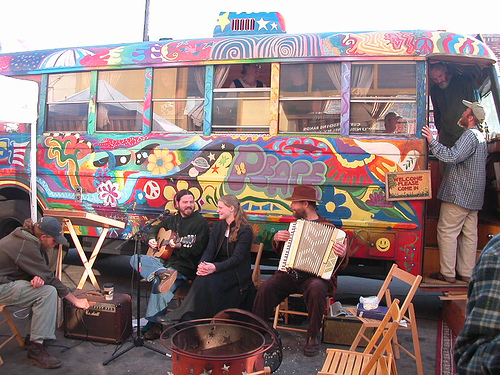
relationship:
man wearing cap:
[0, 215, 90, 368] [33, 211, 71, 251]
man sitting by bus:
[129, 189, 210, 340] [1, 6, 496, 252]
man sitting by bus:
[0, 215, 90, 368] [1, 6, 496, 252]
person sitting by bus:
[156, 193, 256, 330] [1, 6, 496, 252]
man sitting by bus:
[248, 184, 348, 357] [1, 6, 496, 252]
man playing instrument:
[248, 184, 348, 357] [277, 219, 345, 279]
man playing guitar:
[129, 189, 210, 340] [145, 225, 197, 257]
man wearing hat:
[425, 95, 488, 281] [456, 93, 493, 122]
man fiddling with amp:
[2, 216, 98, 350] [63, 288, 133, 343]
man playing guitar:
[129, 189, 210, 340] [138, 221, 201, 261]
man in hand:
[269, 188, 339, 334] [168, 239, 177, 249]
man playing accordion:
[269, 188, 339, 334] [261, 216, 374, 285]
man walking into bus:
[420, 100, 487, 284] [1, 6, 496, 252]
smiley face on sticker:
[376, 229, 388, 257] [375, 235, 391, 253]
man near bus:
[0, 215, 90, 368] [0, 7, 498, 279]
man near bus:
[129, 189, 210, 340] [0, 7, 498, 279]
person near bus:
[156, 193, 256, 330] [0, 7, 498, 279]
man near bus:
[248, 184, 348, 357] [0, 7, 498, 279]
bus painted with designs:
[0, 7, 498, 279] [66, 132, 183, 175]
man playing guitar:
[132, 186, 194, 342] [134, 218, 220, 258]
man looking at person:
[129, 189, 210, 340] [144, 194, 255, 330]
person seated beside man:
[144, 194, 255, 330] [129, 189, 210, 340]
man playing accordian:
[248, 184, 348, 357] [277, 215, 347, 279]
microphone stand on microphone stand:
[101, 205, 173, 370] [103, 233, 172, 366]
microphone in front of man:
[127, 202, 172, 242] [126, 189, 210, 335]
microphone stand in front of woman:
[101, 205, 173, 370] [144, 196, 254, 341]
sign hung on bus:
[388, 172, 435, 204] [39, 103, 359, 186]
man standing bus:
[420, 100, 487, 284] [0, 7, 498, 279]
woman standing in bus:
[224, 63, 267, 106] [0, 7, 498, 279]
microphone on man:
[114, 209, 170, 252] [129, 189, 210, 340]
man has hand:
[129, 189, 210, 340] [166, 236, 184, 248]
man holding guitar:
[129, 189, 210, 340] [147, 221, 200, 263]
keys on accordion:
[278, 219, 297, 271] [270, 214, 354, 289]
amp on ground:
[63, 289, 133, 345] [2, 248, 444, 373]